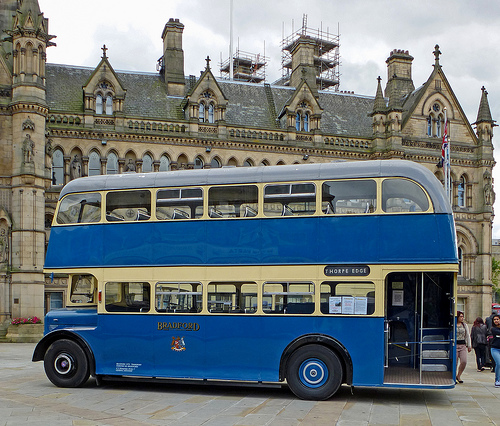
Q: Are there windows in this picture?
A: Yes, there is a window.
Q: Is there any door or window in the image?
A: Yes, there is a window.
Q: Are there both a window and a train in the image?
A: No, there is a window but no trains.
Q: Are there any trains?
A: No, there are no trains.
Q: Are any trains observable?
A: No, there are no trains.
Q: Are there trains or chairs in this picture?
A: No, there are no trains or chairs.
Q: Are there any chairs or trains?
A: No, there are no trains or chairs.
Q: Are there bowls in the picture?
A: No, there are no bowls.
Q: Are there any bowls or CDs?
A: No, there are no bowls or cds.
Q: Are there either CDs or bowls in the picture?
A: No, there are no bowls or cds.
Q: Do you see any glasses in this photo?
A: No, there are no glasses.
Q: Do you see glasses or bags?
A: No, there are no glasses or bags.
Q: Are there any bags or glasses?
A: No, there are no glasses or bags.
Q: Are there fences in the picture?
A: No, there are no fences.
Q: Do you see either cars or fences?
A: No, there are no fences or cars.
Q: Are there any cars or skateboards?
A: No, there are no cars or skateboards.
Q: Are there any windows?
A: Yes, there is a window.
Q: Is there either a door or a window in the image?
A: Yes, there is a window.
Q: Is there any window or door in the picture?
A: Yes, there is a window.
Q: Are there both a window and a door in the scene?
A: Yes, there are both a window and a door.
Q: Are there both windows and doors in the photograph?
A: Yes, there are both a window and doors.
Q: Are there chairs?
A: No, there are no chairs.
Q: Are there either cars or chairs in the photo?
A: No, there are no chairs or cars.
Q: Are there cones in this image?
A: No, there are no cones.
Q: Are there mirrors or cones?
A: No, there are no cones or mirrors.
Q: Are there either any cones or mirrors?
A: No, there are no cones or mirrors.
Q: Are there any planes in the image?
A: No, there are no planes.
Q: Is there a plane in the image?
A: No, there are no airplanes.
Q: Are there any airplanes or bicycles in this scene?
A: No, there are no airplanes or bicycles.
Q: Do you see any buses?
A: Yes, there is a bus.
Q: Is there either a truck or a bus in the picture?
A: Yes, there is a bus.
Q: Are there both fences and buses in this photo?
A: No, there is a bus but no fences.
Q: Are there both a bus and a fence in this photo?
A: No, there is a bus but no fences.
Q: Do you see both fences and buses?
A: No, there is a bus but no fences.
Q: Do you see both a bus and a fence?
A: No, there is a bus but no fences.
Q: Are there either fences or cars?
A: No, there are no cars or fences.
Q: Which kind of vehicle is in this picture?
A: The vehicle is a bus.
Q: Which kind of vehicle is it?
A: The vehicle is a bus.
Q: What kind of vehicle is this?
A: This is a bus.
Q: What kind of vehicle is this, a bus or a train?
A: This is a bus.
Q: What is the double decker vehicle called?
A: The vehicle is a bus.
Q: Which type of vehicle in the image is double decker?
A: The vehicle is a bus.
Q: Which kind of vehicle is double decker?
A: The vehicle is a bus.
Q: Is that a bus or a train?
A: That is a bus.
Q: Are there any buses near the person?
A: Yes, there is a bus near the person.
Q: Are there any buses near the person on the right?
A: Yes, there is a bus near the person.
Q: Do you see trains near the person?
A: No, there is a bus near the person.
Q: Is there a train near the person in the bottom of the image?
A: No, there is a bus near the person.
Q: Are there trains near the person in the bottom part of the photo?
A: No, there is a bus near the person.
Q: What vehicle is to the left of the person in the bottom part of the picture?
A: The vehicle is a bus.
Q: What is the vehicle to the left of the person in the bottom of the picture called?
A: The vehicle is a bus.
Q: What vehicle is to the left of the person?
A: The vehicle is a bus.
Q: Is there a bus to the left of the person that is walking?
A: Yes, there is a bus to the left of the person.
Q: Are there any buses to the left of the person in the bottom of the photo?
A: Yes, there is a bus to the left of the person.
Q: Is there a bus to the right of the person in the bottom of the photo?
A: No, the bus is to the left of the person.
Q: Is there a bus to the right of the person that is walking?
A: No, the bus is to the left of the person.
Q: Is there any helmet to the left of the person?
A: No, there is a bus to the left of the person.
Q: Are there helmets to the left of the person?
A: No, there is a bus to the left of the person.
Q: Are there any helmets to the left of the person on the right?
A: No, there is a bus to the left of the person.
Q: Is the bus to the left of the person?
A: Yes, the bus is to the left of the person.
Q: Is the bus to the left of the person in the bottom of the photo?
A: Yes, the bus is to the left of the person.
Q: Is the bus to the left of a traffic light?
A: No, the bus is to the left of the person.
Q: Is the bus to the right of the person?
A: No, the bus is to the left of the person.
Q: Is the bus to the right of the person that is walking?
A: No, the bus is to the left of the person.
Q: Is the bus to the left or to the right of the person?
A: The bus is to the left of the person.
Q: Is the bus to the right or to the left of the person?
A: The bus is to the left of the person.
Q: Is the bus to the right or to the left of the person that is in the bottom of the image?
A: The bus is to the left of the person.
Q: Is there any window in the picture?
A: Yes, there is a window.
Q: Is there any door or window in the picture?
A: Yes, there is a window.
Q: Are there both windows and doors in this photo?
A: Yes, there are both a window and a door.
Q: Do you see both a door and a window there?
A: Yes, there are both a window and a door.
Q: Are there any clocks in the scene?
A: No, there are no clocks.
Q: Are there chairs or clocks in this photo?
A: No, there are no clocks or chairs.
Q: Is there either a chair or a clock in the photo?
A: No, there are no clocks or chairs.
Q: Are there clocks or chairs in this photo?
A: No, there are no clocks or chairs.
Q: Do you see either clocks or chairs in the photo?
A: No, there are no clocks or chairs.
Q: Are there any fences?
A: No, there are no fences.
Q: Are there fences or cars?
A: No, there are no fences or cars.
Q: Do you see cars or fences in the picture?
A: No, there are no fences or cars.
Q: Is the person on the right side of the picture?
A: Yes, the person is on the right of the image.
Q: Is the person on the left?
A: No, the person is on the right of the image.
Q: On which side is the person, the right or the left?
A: The person is on the right of the image.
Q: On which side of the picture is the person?
A: The person is on the right of the image.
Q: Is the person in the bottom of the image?
A: Yes, the person is in the bottom of the image.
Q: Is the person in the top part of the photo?
A: No, the person is in the bottom of the image.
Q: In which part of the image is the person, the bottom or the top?
A: The person is in the bottom of the image.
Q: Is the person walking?
A: Yes, the person is walking.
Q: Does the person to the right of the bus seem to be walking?
A: Yes, the person is walking.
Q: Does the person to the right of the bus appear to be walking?
A: Yes, the person is walking.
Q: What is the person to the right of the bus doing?
A: The person is walking.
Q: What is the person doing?
A: The person is walking.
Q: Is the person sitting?
A: No, the person is walking.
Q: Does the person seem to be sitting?
A: No, the person is walking.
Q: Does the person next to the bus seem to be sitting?
A: No, the person is walking.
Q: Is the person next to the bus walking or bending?
A: The person is walking.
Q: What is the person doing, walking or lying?
A: The person is walking.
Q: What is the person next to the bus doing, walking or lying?
A: The person is walking.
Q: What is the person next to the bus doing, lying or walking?
A: The person is walking.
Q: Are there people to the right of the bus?
A: Yes, there is a person to the right of the bus.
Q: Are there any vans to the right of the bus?
A: No, there is a person to the right of the bus.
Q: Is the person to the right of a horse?
A: No, the person is to the right of the bus.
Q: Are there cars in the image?
A: No, there are no cars.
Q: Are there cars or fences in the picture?
A: No, there are no cars or fences.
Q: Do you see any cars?
A: No, there are no cars.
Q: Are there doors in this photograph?
A: Yes, there is a door.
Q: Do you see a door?
A: Yes, there is a door.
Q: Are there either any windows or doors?
A: Yes, there is a door.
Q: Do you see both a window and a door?
A: Yes, there are both a door and a window.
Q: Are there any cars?
A: No, there are no cars.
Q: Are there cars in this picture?
A: No, there are no cars.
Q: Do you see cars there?
A: No, there are no cars.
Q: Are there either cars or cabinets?
A: No, there are no cars or cabinets.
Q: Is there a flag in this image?
A: Yes, there is a flag.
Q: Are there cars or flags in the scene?
A: Yes, there is a flag.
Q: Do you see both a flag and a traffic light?
A: No, there is a flag but no traffic lights.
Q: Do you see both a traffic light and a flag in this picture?
A: No, there is a flag but no traffic lights.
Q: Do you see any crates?
A: No, there are no crates.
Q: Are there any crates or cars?
A: No, there are no crates or cars.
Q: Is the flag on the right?
A: Yes, the flag is on the right of the image.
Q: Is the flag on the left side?
A: No, the flag is on the right of the image.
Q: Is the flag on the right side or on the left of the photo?
A: The flag is on the right of the image.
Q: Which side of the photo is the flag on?
A: The flag is on the right of the image.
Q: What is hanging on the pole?
A: The flag is hanging on the pole.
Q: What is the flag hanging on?
A: The flag is hanging on the pole.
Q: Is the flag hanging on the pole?
A: Yes, the flag is hanging on the pole.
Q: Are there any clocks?
A: No, there are no clocks.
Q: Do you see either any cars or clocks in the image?
A: No, there are no clocks or cars.